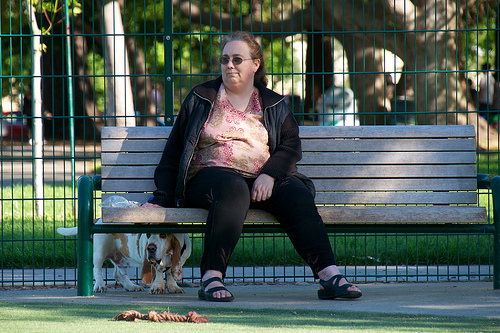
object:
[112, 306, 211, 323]
toy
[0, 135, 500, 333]
ground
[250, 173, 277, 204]
hand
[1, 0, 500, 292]
fence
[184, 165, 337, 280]
pants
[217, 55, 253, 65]
sunglasses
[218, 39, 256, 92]
face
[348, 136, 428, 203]
shining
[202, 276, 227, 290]
black strap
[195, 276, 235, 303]
sandal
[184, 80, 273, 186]
shirt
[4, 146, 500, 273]
grass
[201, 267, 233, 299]
foot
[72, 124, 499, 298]
bench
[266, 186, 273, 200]
finger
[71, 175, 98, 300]
green support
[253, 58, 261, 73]
ear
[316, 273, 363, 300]
sandals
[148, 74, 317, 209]
black coat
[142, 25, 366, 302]
woman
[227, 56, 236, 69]
nose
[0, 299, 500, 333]
grass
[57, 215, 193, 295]
dog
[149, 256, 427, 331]
shadows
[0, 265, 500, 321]
surface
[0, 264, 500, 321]
path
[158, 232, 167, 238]
black eyes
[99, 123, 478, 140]
slats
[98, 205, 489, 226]
seat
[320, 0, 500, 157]
trees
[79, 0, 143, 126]
trees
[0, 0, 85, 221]
trees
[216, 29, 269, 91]
head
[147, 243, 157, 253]
nose